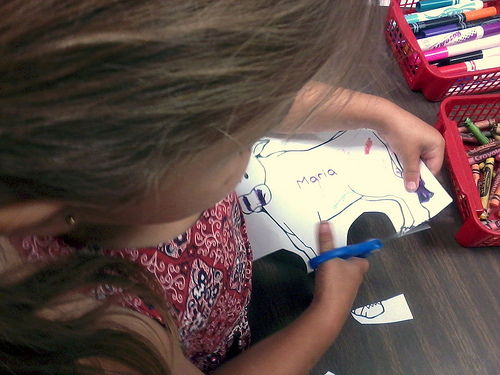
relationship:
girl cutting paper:
[3, 0, 445, 374] [235, 128, 454, 325]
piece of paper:
[351, 294, 415, 327] [235, 128, 454, 325]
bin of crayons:
[439, 91, 499, 247] [457, 115, 497, 234]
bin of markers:
[383, 0, 499, 104] [402, 2, 499, 73]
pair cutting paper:
[308, 222, 436, 266] [235, 128, 454, 325]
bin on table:
[439, 91, 499, 247] [249, 2, 499, 373]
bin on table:
[383, 0, 499, 104] [249, 2, 499, 373]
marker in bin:
[439, 57, 499, 74] [383, 0, 499, 104]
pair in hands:
[308, 222, 436, 266] [308, 111, 444, 302]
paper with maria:
[235, 128, 454, 325] [295, 166, 339, 189]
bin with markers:
[383, 0, 499, 104] [402, 2, 499, 73]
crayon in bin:
[464, 118, 489, 141] [439, 91, 499, 247]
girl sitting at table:
[3, 0, 445, 374] [249, 2, 499, 373]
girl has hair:
[3, 0, 445, 374] [0, 3, 377, 372]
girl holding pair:
[3, 0, 445, 374] [308, 222, 436, 266]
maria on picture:
[295, 166, 339, 189] [232, 124, 429, 268]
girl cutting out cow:
[3, 0, 445, 374] [232, 124, 429, 268]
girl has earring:
[3, 0, 445, 374] [64, 213, 78, 230]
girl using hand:
[3, 0, 445, 374] [312, 221, 371, 300]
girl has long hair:
[3, 0, 445, 374] [0, 3, 377, 372]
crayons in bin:
[457, 115, 497, 234] [439, 91, 499, 247]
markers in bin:
[402, 2, 499, 73] [383, 0, 499, 104]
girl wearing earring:
[3, 0, 445, 374] [64, 213, 78, 230]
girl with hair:
[3, 0, 445, 374] [0, 3, 377, 372]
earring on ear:
[64, 213, 78, 230] [42, 217, 74, 234]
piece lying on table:
[351, 294, 415, 327] [249, 2, 499, 373]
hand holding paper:
[387, 104, 446, 192] [235, 128, 454, 325]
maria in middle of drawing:
[295, 166, 339, 189] [232, 124, 429, 268]